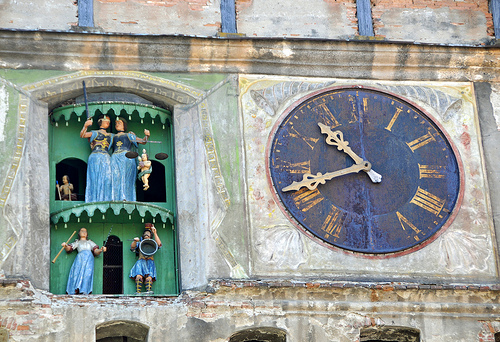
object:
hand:
[280, 165, 374, 195]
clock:
[263, 89, 455, 260]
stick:
[49, 226, 73, 263]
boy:
[50, 176, 80, 206]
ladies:
[111, 118, 153, 202]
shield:
[139, 236, 160, 257]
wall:
[0, 278, 499, 342]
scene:
[0, 65, 241, 289]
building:
[0, 0, 500, 342]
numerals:
[347, 98, 374, 126]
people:
[81, 117, 111, 200]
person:
[57, 226, 104, 296]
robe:
[127, 251, 161, 279]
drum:
[96, 246, 106, 258]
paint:
[187, 35, 266, 73]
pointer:
[317, 120, 379, 181]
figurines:
[29, 74, 183, 305]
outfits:
[83, 149, 114, 203]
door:
[56, 159, 81, 198]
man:
[110, 138, 133, 207]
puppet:
[127, 149, 153, 192]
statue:
[127, 224, 161, 295]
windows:
[101, 236, 127, 295]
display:
[35, 285, 194, 311]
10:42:
[279, 118, 382, 194]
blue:
[85, 152, 139, 209]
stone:
[222, 1, 236, 38]